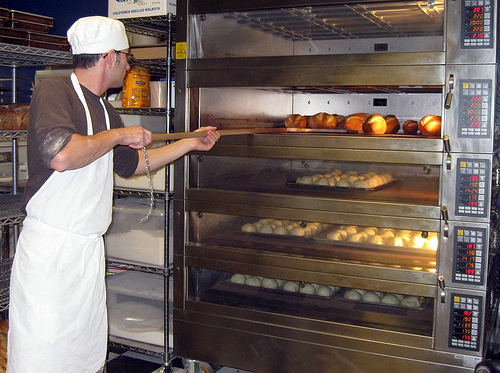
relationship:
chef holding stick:
[3, 15, 221, 373] [132, 122, 352, 144]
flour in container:
[100, 220, 175, 272] [99, 190, 174, 270]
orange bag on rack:
[125, 69, 156, 108] [74, 65, 177, 124]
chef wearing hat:
[3, 15, 221, 373] [65, 7, 155, 61]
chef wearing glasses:
[2, 15, 227, 369] [110, 45, 137, 60]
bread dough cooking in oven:
[294, 164, 395, 191] [175, 2, 497, 371]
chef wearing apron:
[3, 15, 221, 373] [4, 73, 118, 371]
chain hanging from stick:
[118, 149, 173, 230] [123, 103, 297, 153]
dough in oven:
[298, 169, 390, 189] [170, 1, 462, 371]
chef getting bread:
[3, 15, 221, 373] [290, 103, 392, 131]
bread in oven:
[290, 103, 392, 131] [215, 95, 427, 186]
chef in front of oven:
[3, 15, 221, 373] [175, 2, 497, 371]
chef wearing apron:
[3, 15, 221, 373] [0, 77, 127, 371]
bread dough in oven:
[350, 178, 372, 191] [175, 2, 497, 371]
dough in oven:
[333, 177, 353, 189] [175, 2, 497, 371]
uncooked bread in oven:
[327, 177, 338, 187] [175, 2, 497, 371]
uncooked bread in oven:
[314, 177, 328, 184] [175, 2, 497, 371]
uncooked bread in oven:
[295, 175, 313, 185] [175, 2, 497, 371]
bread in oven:
[283, 113, 443, 135] [175, 2, 497, 371]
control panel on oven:
[457, 81, 489, 137] [192, 204, 427, 267]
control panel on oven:
[444, 283, 482, 357] [203, 267, 483, 359]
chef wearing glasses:
[3, 15, 221, 373] [100, 47, 135, 62]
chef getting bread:
[3, 15, 221, 373] [282, 111, 439, 136]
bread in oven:
[282, 111, 439, 136] [175, 2, 497, 371]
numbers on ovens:
[446, 4, 494, 354] [155, 29, 492, 370]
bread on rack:
[360, 113, 389, 137] [195, 84, 440, 144]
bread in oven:
[360, 113, 389, 137] [199, 69, 454, 153]